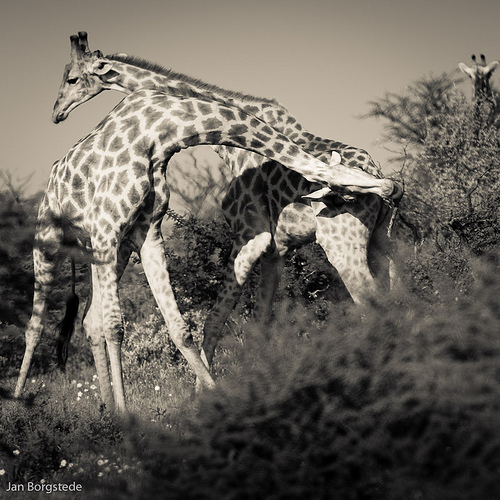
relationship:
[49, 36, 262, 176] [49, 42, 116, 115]
giraffe has head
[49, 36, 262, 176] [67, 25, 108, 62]
giraffe has horn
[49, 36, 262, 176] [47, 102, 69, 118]
giraffe has mouth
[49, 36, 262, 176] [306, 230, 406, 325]
giraffe has leg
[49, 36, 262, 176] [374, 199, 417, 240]
giraffe has tail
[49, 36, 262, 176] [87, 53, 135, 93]
giraffe has ear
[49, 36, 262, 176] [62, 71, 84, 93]
giraffe has eye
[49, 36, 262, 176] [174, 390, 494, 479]
giraffe in field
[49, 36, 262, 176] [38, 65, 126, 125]
giraffe has face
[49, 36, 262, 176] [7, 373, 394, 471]
giraffe in wild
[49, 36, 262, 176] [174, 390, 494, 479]
giraffe in africa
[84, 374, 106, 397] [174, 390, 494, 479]
flowers in field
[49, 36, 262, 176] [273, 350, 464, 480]
giraffe near bush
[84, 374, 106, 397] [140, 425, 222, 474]
flowers in grass